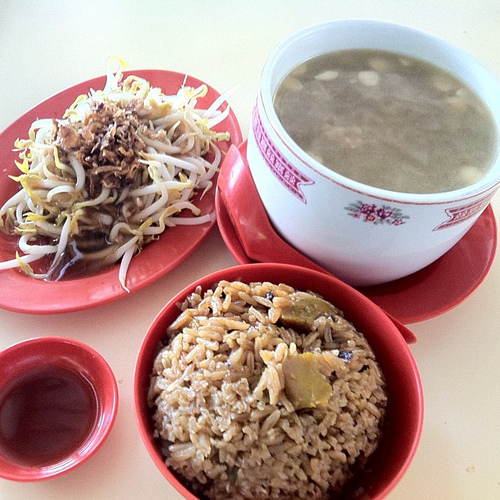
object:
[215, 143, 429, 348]
spoon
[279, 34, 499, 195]
soup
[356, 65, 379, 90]
mushrooms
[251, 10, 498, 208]
bowl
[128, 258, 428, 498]
bowl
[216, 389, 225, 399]
rice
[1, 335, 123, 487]
bowl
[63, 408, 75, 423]
sauce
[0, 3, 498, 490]
food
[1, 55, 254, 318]
plate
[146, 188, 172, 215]
vegetables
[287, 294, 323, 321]
vegetables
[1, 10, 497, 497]
table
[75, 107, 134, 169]
meat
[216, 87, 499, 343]
bowl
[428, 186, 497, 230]
markings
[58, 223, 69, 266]
sprouts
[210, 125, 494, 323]
dish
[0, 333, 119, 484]
dish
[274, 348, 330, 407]
meat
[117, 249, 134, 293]
bean sprouts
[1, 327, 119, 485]
cup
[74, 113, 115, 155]
toppings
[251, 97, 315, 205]
charcters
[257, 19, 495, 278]
cup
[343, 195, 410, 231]
designs